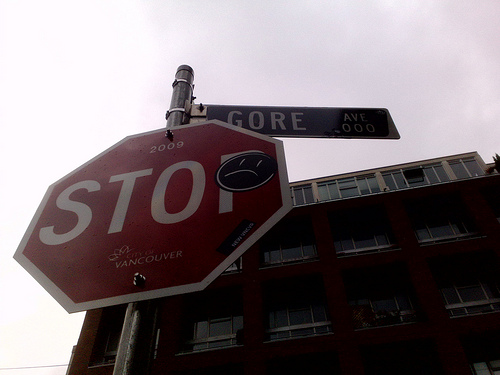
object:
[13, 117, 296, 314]
sign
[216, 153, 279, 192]
sticker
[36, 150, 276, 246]
print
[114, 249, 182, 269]
text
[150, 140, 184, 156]
print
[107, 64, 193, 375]
pole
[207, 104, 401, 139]
sign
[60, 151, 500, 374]
building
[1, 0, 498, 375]
sky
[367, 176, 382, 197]
window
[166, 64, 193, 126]
top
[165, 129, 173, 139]
screw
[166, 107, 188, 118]
bracket